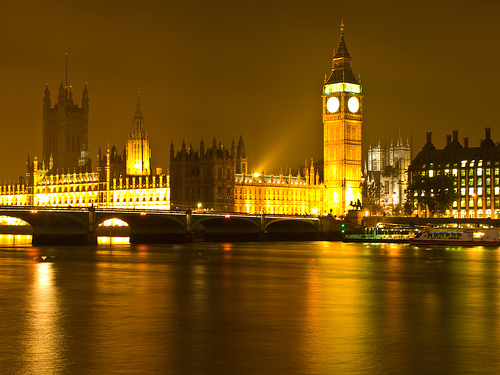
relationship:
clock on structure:
[323, 95, 343, 117] [320, 20, 367, 185]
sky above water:
[1, 5, 499, 168] [3, 233, 497, 373]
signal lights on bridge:
[23, 205, 43, 216] [2, 198, 346, 250]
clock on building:
[325, 96, 340, 113] [220, 40, 376, 218]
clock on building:
[344, 93, 359, 115] [229, 43, 369, 220]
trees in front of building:
[395, 169, 453, 223] [396, 118, 497, 228]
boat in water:
[340, 213, 415, 243] [3, 233, 497, 373]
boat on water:
[403, 220, 496, 247] [3, 233, 497, 373]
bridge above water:
[3, 200, 340, 261] [3, 233, 497, 373]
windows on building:
[414, 160, 496, 212] [405, 123, 497, 236]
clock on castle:
[325, 96, 340, 113] [358, 125, 416, 219]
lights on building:
[410, 148, 498, 219] [405, 123, 497, 236]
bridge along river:
[0, 203, 329, 246] [3, 240, 496, 366]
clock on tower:
[347, 96, 360, 113] [315, 32, 374, 220]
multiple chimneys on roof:
[19, 102, 481, 243] [28, 78, 194, 161]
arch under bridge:
[33, 168, 201, 273] [28, 230, 490, 267]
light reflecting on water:
[9, 232, 483, 375] [2, 211, 498, 363]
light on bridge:
[313, 174, 481, 275] [42, 212, 446, 317]